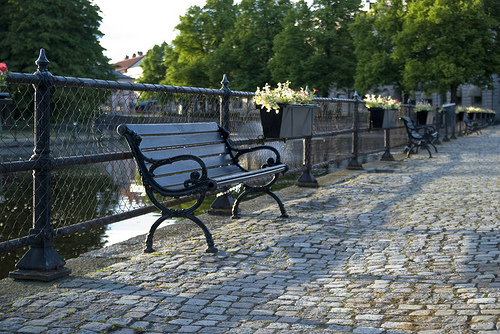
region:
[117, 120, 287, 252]
metal bench with black metal rails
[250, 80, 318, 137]
black metal flower holder on fence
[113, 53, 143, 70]
red roof on white building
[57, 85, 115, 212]
black chain link fence by pond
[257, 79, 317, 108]
whit red and yellow flower in holder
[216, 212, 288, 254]
grey brick sidewalk under bench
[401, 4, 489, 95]
tall green tree by pond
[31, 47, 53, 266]
pointed black fence pole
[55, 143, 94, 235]
pond behind black metal fence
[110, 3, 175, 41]
clear sky over pond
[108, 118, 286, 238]
the bench is empty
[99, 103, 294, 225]
the bench is black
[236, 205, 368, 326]
the gray, stoned ground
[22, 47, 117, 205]
the fence is black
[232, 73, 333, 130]
the flowers are white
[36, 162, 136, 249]
the water is murky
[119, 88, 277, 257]
black bench is empty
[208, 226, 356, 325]
shadows on the ground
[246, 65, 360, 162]
flower pot attached to the fence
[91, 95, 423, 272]
a fence behind the bench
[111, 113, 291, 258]
Bench on walkway near wire fence.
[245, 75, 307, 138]
Potted plant in gray container mounted on fence.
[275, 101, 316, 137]
Gray container holding potted plant.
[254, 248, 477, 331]
A brick paved walkway.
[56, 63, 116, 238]
Wire fence behind bench.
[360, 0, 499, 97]
Trees growing along walkway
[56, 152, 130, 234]
River behind fence and bench.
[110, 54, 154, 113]
Houses across river in distance.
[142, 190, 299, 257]
Four legs supporting bench.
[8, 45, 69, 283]
Post helping to support wire fence.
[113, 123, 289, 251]
Wood and metal bench close to the camera.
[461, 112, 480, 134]
Furthest wood and metal bench.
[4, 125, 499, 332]
A light colored brick walkway.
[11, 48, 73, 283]
Green iron post to the left of the closest bench.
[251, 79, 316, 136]
The first flower planter box with flowers to the right of the first bench.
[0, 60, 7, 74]
A single red flower bloom to the far left of the first bench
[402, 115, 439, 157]
The middle wood and metal bench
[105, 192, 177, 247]
White shiny reflection on the water top.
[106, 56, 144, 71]
Red roof through the trees.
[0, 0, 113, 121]
Very large dark green tree left from all the others trees.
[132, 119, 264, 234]
this is a bench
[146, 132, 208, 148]
this is a wood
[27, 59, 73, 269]
this is a pole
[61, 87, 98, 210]
this is a fence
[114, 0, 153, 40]
this is the sky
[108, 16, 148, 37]
the sky is blue in color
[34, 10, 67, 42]
this is a tree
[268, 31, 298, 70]
the leaves are green in color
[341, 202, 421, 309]
this is the ground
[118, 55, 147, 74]
this is a building